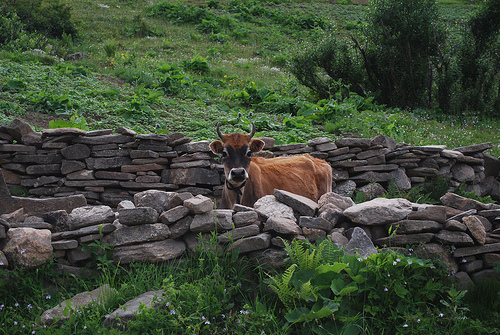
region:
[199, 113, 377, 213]
a brown cow with a black face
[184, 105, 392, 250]
a cow standing by a rock wall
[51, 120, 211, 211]
rocks stacked together to make a wall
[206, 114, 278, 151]
horns on the head of a cow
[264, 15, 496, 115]
a heavily dense wooded area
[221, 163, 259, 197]
the nose of a cow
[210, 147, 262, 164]
big black eyes of a cow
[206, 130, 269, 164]
ears of a cow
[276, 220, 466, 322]
green shrubs in front of a stone wall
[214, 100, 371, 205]
a cow looking over a stone wall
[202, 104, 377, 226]
the cow is brown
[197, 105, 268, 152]
the cow has horns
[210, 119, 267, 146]
the cow has horns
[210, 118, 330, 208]
a brown cow standing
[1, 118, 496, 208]
a stone built wall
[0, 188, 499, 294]
a stone built wall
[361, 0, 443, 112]
large green tree in distance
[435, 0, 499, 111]
large green tree in distance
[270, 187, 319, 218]
a large grey stone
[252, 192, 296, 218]
a large grey stone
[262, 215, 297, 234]
a large grey stone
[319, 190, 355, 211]
a large grey stone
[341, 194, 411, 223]
a large grey stone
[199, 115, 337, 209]
the cow standing by the brick wall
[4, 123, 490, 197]
a stone wall behind the cow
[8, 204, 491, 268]
the stone wall in front of the cow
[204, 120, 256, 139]
the horns attacked to the head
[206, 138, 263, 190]
the relaxed face of the cow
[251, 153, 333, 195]
the body of the cow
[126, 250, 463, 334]
the green plants in front of the wall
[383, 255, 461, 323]
the little flowers attached to the plant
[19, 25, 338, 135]
the green plants attached to the hill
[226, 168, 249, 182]
the nose of the cow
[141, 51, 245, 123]
green grass on a hill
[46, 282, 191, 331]
two stones in the tall grass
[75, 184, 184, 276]
stones stacked on top of each other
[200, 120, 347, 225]
cow in a stone pen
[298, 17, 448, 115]
trees at the bottom of the hill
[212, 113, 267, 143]
two small curved horns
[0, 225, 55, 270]
one large bright colored rock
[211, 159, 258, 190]
cows black nose circle in white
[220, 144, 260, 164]
cows big brown eyes circled in white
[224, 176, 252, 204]
rope tied around cows neck